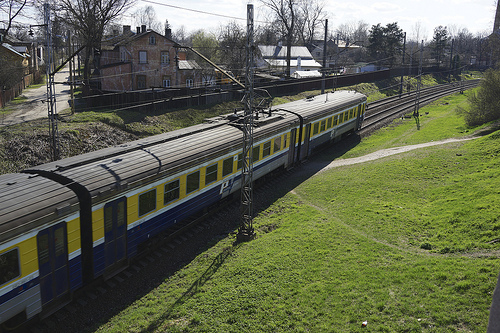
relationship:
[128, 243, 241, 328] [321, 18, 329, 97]
shadow of pole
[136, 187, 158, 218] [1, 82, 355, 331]
window of train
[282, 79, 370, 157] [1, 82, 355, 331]
car of train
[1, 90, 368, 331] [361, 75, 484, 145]
train on tracks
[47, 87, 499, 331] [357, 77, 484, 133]
hill by train tracks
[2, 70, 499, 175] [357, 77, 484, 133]
hill by train tracks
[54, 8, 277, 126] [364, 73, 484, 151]
house near tracks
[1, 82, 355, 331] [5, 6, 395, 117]
train pass city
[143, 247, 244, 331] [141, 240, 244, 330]
shadow cast ground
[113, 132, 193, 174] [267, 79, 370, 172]
roof on top train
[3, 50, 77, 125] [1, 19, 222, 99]
road between houses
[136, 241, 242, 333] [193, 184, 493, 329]
shadow on grass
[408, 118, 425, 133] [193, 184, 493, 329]
shadows on grass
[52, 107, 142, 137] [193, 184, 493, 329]
shadows on grass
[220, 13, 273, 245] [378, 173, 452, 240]
pole on grass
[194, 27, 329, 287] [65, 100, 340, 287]
poles aside train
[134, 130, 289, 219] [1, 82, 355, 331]
windows aside train